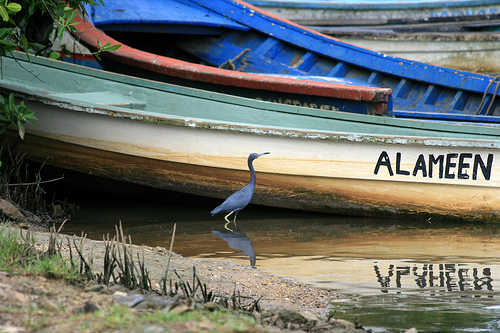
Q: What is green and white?
A: Canoe.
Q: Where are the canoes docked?
A: Shore.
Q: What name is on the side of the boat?
A: Alameen.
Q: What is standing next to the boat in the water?
A: A black bird.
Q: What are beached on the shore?
A: Two boats.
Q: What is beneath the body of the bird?
A: Two legs.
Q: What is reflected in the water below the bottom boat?
A: The boat's name.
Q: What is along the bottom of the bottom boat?
A: Algae.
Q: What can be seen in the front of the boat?
A: A bench.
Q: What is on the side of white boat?
A: Letters.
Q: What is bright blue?
A: Boat on the left.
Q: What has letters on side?
A: Boat on right.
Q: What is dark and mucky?
A: Water.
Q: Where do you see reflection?
A: Water.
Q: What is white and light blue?
A: Boat on right.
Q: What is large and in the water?
A: Boats.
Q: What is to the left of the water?
A: Dirt shore.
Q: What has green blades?
A: Grass.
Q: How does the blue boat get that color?
A: By being painted.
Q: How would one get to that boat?
A: Through the water.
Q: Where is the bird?
A: In the water.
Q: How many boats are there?
A: Two.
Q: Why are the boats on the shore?
A: They are broke.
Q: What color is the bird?
A: Gray.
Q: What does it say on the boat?
A: Alameen.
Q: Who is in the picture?
A: Only the bird.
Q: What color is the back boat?
A: Blue and red.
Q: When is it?
A: Day time.